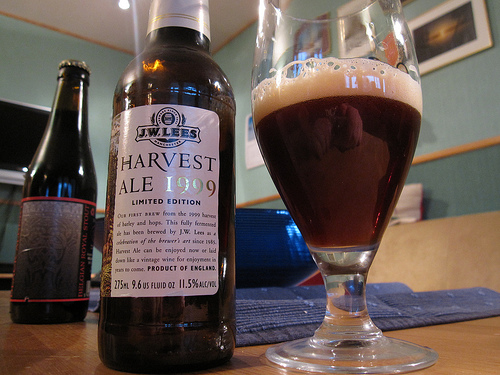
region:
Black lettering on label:
[119, 150, 216, 175]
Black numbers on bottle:
[113, 278, 123, 290]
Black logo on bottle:
[131, 106, 202, 150]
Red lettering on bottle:
[76, 200, 91, 300]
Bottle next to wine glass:
[93, 0, 426, 373]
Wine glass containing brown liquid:
[247, 0, 442, 372]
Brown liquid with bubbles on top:
[251, 51, 426, 251]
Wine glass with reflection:
[246, 0, 426, 368]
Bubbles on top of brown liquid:
[251, 55, 423, 255]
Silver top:
[58, 56, 92, 73]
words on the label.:
[143, 263, 211, 273]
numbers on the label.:
[165, 175, 213, 191]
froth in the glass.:
[267, 81, 418, 90]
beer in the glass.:
[319, 128, 383, 199]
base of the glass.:
[295, 327, 405, 370]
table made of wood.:
[25, 334, 80, 374]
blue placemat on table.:
[257, 295, 309, 327]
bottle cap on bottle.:
[57, 53, 92, 70]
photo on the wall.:
[420, 7, 477, 55]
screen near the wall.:
[3, 105, 30, 162]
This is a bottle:
[1, 36, 103, 336]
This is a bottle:
[92, 9, 243, 371]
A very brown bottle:
[8, 36, 95, 327]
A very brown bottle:
[95, 11, 247, 371]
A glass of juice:
[248, 5, 442, 367]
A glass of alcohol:
[254, 0, 441, 374]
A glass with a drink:
[255, 5, 440, 367]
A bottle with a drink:
[1, 41, 96, 322]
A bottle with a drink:
[90, 5, 240, 371]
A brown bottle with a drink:
[1, 39, 102, 327]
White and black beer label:
[110, 104, 222, 299]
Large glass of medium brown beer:
[246, 0, 446, 373]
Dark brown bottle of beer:
[11, 45, 96, 330]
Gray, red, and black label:
[12, 198, 94, 303]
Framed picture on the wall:
[407, 0, 495, 86]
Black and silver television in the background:
[0, 96, 54, 192]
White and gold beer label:
[132, 0, 227, 44]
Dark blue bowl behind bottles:
[79, 210, 334, 291]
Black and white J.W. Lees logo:
[127, 102, 210, 157]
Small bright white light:
[115, 0, 137, 12]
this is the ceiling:
[79, 3, 107, 23]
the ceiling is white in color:
[85, 5, 111, 32]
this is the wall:
[8, 39, 33, 83]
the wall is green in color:
[9, 31, 39, 81]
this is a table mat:
[386, 281, 419, 318]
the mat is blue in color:
[246, 293, 273, 318]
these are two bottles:
[28, 2, 233, 360]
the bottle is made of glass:
[134, 310, 184, 342]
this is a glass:
[256, 2, 428, 349]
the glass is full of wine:
[298, 119, 368, 174]